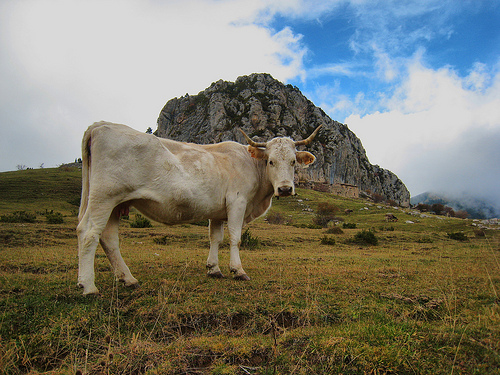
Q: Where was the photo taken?
A: It was taken at the field.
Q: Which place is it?
A: It is a field.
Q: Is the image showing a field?
A: Yes, it is showing a field.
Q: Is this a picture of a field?
A: Yes, it is showing a field.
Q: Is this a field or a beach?
A: It is a field.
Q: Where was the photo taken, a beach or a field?
A: It was taken at a field.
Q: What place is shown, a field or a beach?
A: It is a field.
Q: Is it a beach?
A: No, it is a field.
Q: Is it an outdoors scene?
A: Yes, it is outdoors.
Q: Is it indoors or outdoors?
A: It is outdoors.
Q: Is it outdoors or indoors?
A: It is outdoors.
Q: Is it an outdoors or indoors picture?
A: It is outdoors.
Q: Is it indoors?
A: No, it is outdoors.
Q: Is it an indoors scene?
A: No, it is outdoors.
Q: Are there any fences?
A: No, there are no fences.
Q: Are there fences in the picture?
A: No, there are no fences.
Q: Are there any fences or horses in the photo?
A: No, there are no fences or horses.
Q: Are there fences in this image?
A: No, there are no fences.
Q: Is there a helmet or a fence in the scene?
A: No, there are no fences or helmets.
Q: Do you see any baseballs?
A: No, there are no baseballs.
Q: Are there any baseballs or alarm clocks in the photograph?
A: No, there are no baseballs or alarm clocks.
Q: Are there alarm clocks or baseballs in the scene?
A: No, there are no baseballs or alarm clocks.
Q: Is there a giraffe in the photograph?
A: No, there are no giraffes.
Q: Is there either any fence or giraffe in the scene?
A: No, there are no giraffes or fences.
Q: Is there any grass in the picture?
A: Yes, there is grass.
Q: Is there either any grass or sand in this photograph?
A: Yes, there is grass.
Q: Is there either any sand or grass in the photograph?
A: Yes, there is grass.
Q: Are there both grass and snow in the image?
A: No, there is grass but no snow.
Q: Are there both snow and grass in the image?
A: No, there is grass but no snow.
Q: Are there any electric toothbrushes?
A: No, there are no electric toothbrushes.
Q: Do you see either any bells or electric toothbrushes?
A: No, there are no electric toothbrushes or bells.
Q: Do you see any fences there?
A: No, there are no fences.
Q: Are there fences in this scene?
A: No, there are no fences.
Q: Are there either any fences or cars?
A: No, there are no fences or cars.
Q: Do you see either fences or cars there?
A: No, there are no fences or cars.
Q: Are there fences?
A: No, there are no fences.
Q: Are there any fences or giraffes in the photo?
A: No, there are no fences or giraffes.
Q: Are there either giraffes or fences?
A: No, there are no fences or giraffes.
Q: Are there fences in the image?
A: No, there are no fences.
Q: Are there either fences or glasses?
A: No, there are no fences or glasses.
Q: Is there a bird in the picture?
A: No, there are no birds.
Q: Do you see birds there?
A: No, there are no birds.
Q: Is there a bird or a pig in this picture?
A: No, there are no birds or pigs.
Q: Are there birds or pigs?
A: No, there are no birds or pigs.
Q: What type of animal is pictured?
A: The animal is a bull.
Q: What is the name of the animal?
A: The animal is a bull.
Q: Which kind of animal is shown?
A: The animal is a bull.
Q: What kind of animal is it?
A: The animal is a bull.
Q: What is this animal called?
A: This is a bull.